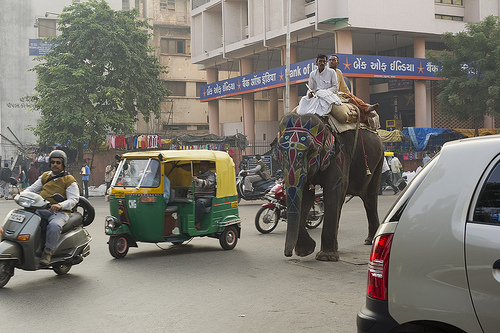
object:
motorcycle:
[0, 189, 95, 289]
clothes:
[109, 134, 162, 149]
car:
[355, 133, 500, 333]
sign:
[200, 53, 483, 101]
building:
[0, 0, 500, 158]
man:
[13, 150, 80, 265]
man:
[296, 53, 343, 116]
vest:
[40, 170, 80, 215]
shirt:
[22, 170, 79, 215]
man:
[80, 159, 91, 199]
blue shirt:
[82, 165, 90, 182]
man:
[422, 151, 432, 167]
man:
[391, 152, 403, 187]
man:
[329, 54, 380, 112]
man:
[243, 155, 271, 193]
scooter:
[236, 169, 279, 203]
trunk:
[284, 170, 307, 257]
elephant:
[270, 113, 384, 262]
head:
[255, 182, 285, 234]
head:
[0, 207, 38, 289]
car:
[104, 150, 241, 259]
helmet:
[49, 150, 68, 168]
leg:
[358, 180, 380, 234]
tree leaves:
[25, 0, 162, 150]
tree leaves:
[425, 14, 498, 137]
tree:
[24, 0, 174, 196]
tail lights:
[367, 233, 394, 301]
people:
[296, 54, 380, 117]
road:
[0, 242, 364, 333]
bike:
[255, 169, 325, 234]